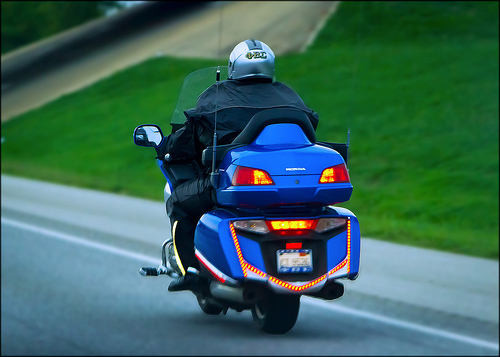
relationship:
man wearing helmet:
[151, 31, 327, 291] [226, 36, 276, 79]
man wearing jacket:
[151, 31, 327, 291] [154, 76, 324, 178]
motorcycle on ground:
[132, 66, 361, 335] [0, 176, 499, 357]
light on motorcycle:
[317, 163, 349, 183] [129, 35, 362, 335]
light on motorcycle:
[258, 210, 323, 235] [129, 35, 362, 335]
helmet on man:
[222, 35, 282, 85] [165, 39, 317, 291]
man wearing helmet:
[165, 39, 317, 291] [227, 38, 275, 80]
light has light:
[231, 165, 275, 185] [318, 163, 350, 183]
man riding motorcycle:
[165, 39, 317, 291] [132, 66, 361, 335]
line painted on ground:
[6, 209, 127, 268] [0, 176, 499, 357]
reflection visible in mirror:
[142, 122, 159, 142] [133, 125, 162, 147]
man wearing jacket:
[165, 39, 317, 291] [148, 27, 356, 294]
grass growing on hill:
[0, 0, 498, 260] [0, 0, 497, 325]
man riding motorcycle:
[151, 31, 327, 291] [129, 35, 362, 335]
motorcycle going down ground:
[132, 66, 361, 335] [0, 176, 499, 357]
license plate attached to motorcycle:
[276, 245, 315, 277] [123, 60, 391, 315]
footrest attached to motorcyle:
[138, 264, 169, 276] [133, 120, 366, 332]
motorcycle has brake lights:
[129, 35, 362, 335] [231, 161, 353, 188]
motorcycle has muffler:
[132, 66, 361, 335] [206, 280, 254, 309]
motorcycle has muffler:
[132, 66, 361, 335] [305, 270, 347, 304]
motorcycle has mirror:
[129, 35, 362, 335] [131, 122, 165, 149]